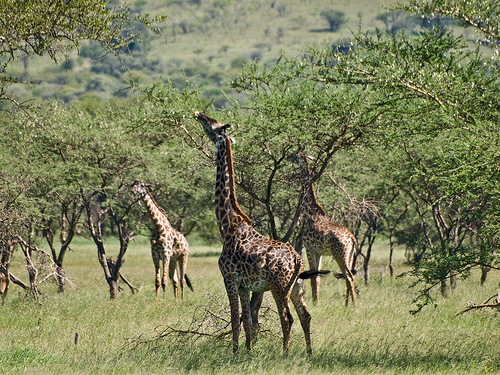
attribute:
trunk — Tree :
[0, 237, 17, 294]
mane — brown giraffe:
[226, 135, 251, 225]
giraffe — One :
[198, 115, 317, 365]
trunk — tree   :
[98, 278, 117, 298]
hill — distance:
[0, 2, 499, 92]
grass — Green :
[5, 262, 496, 371]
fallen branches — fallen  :
[141, 299, 284, 344]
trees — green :
[346, 28, 497, 294]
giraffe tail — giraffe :
[275, 254, 312, 313]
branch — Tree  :
[154, 311, 278, 344]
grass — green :
[316, 307, 436, 354]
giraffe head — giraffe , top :
[193, 110, 232, 145]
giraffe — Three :
[116, 176, 198, 336]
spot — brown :
[230, 226, 250, 242]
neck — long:
[209, 141, 249, 219]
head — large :
[192, 98, 244, 150]